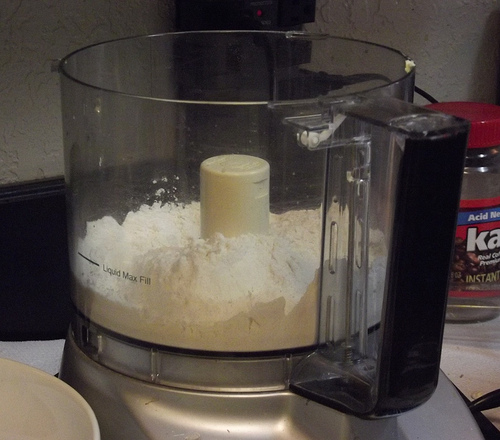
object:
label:
[447, 197, 500, 298]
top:
[417, 101, 500, 122]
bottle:
[420, 101, 499, 326]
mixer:
[58, 30, 414, 354]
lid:
[424, 101, 500, 149]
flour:
[72, 201, 390, 355]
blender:
[58, 30, 485, 440]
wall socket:
[173, 0, 318, 65]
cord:
[465, 390, 499, 413]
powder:
[70, 202, 388, 352]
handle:
[374, 124, 469, 420]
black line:
[76, 252, 99, 267]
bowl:
[0, 357, 100, 440]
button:
[255, 9, 262, 17]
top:
[340, 96, 470, 136]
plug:
[298, 66, 344, 104]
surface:
[175, 0, 316, 31]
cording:
[425, 404, 463, 440]